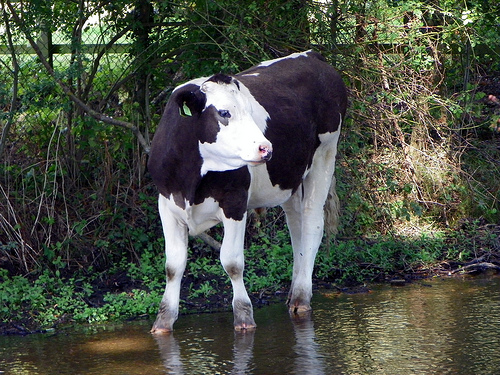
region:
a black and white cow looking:
[133, 47, 345, 333]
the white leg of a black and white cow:
[151, 195, 191, 339]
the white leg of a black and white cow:
[218, 209, 258, 331]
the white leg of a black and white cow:
[287, 141, 327, 316]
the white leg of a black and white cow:
[280, 183, 309, 301]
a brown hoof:
[232, 319, 258, 332]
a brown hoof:
[145, 323, 172, 335]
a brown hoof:
[288, 301, 310, 316]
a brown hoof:
[285, 284, 297, 308]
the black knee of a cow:
[223, 259, 242, 278]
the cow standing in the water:
[146, 45, 347, 335]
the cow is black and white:
[145, 50, 341, 337]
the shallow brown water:
[330, 292, 486, 372]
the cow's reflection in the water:
[147, 322, 318, 372]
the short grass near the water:
[8, 247, 411, 292]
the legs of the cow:
[148, 176, 324, 332]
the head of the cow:
[176, 72, 271, 162]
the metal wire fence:
[0, 12, 140, 137]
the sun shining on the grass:
[375, 116, 440, 232]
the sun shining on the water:
[87, 334, 151, 355]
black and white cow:
[132, 52, 350, 351]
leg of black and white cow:
[206, 208, 261, 343]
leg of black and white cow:
[142, 225, 204, 347]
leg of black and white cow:
[289, 265, 320, 335]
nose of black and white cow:
[230, 134, 280, 176]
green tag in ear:
[184, 106, 196, 123]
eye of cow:
[214, 107, 232, 131]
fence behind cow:
[1, 60, 96, 138]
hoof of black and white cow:
[229, 311, 259, 338]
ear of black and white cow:
[170, 82, 204, 118]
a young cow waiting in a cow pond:
[81, 34, 354, 372]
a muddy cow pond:
[10, 253, 497, 355]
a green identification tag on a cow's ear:
[168, 97, 203, 131]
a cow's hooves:
[152, 281, 330, 366]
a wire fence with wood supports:
[16, 13, 146, 90]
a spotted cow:
[137, 56, 379, 282]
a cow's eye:
[208, 105, 236, 127]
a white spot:
[237, 70, 267, 81]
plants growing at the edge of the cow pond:
[24, 271, 104, 321]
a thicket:
[332, 23, 484, 218]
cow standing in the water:
[109, 32, 361, 342]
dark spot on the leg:
[223, 261, 248, 281]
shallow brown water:
[29, 272, 498, 372]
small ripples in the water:
[346, 307, 410, 362]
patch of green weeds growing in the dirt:
[6, 273, 86, 323]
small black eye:
[218, 106, 233, 118]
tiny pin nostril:
[256, 142, 266, 155]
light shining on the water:
[83, 331, 145, 357]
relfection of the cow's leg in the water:
[293, 318, 322, 373]